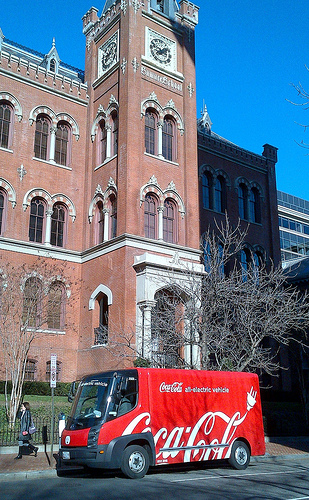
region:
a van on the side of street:
[53, 366, 279, 477]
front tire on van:
[112, 442, 152, 473]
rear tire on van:
[224, 431, 253, 467]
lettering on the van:
[157, 378, 232, 404]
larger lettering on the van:
[132, 407, 238, 459]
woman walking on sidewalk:
[10, 396, 37, 460]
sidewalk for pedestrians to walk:
[1, 462, 43, 467]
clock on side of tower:
[145, 25, 177, 65]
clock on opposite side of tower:
[92, 29, 123, 69]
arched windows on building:
[135, 184, 182, 240]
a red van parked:
[62, 370, 263, 471]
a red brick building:
[11, 3, 276, 376]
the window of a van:
[72, 375, 136, 428]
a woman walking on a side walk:
[13, 401, 34, 456]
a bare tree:
[1, 249, 68, 416]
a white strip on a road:
[160, 472, 305, 484]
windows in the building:
[140, 194, 180, 236]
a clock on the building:
[147, 36, 177, 65]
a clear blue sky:
[194, 9, 307, 101]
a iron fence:
[5, 416, 57, 441]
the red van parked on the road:
[56, 367, 266, 477]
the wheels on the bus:
[118, 440, 250, 476]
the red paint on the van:
[57, 368, 265, 477]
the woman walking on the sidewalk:
[13, 401, 37, 457]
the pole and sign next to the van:
[49, 353, 55, 466]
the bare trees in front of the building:
[0, 208, 308, 429]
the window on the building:
[143, 191, 157, 238]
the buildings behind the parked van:
[0, 0, 308, 381]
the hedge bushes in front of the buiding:
[0, 380, 98, 397]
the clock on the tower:
[144, 26, 177, 69]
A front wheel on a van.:
[119, 445, 149, 477]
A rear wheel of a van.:
[230, 440, 250, 468]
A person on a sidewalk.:
[15, 400, 38, 458]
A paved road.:
[0, 459, 308, 498]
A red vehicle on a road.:
[55, 366, 266, 478]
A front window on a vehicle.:
[68, 380, 110, 420]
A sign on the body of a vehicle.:
[159, 382, 228, 393]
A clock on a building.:
[150, 39, 170, 64]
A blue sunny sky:
[1, 0, 308, 201]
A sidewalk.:
[0, 443, 308, 474]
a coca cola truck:
[47, 361, 277, 470]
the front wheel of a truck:
[107, 419, 176, 475]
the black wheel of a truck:
[221, 420, 277, 465]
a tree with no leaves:
[157, 238, 271, 379]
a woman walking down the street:
[9, 387, 49, 457]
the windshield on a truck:
[52, 354, 157, 434]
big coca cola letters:
[111, 391, 261, 463]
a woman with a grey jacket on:
[14, 391, 49, 439]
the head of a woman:
[17, 396, 46, 415]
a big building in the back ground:
[52, 212, 256, 369]